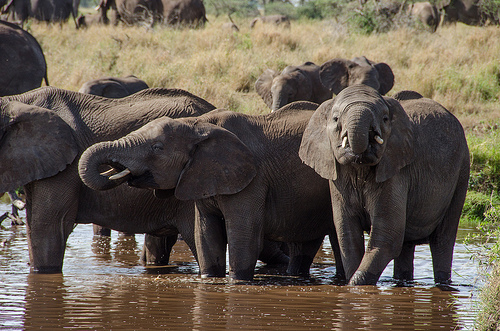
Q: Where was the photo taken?
A: It was taken at the park.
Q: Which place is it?
A: It is a park.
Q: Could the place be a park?
A: Yes, it is a park.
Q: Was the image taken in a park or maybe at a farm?
A: It was taken at a park.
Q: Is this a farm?
A: No, it is a park.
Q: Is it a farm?
A: No, it is a park.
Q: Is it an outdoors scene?
A: Yes, it is outdoors.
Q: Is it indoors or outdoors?
A: It is outdoors.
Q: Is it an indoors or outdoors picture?
A: It is outdoors.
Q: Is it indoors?
A: No, it is outdoors.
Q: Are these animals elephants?
A: Yes, all the animals are elephants.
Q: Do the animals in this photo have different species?
A: No, all the animals are elephants.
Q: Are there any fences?
A: No, there are no fences.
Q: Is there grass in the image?
A: Yes, there is grass.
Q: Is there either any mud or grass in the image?
A: Yes, there is grass.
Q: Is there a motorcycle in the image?
A: No, there are no motorcycles.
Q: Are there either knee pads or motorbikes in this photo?
A: No, there are no motorbikes or knee pads.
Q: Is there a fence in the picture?
A: No, there are no fences.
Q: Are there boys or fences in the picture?
A: No, there are no fences or boys.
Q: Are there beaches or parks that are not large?
A: No, there is a park but it is large.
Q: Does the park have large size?
A: Yes, the park is large.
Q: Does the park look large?
A: Yes, the park is large.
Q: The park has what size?
A: The park is large.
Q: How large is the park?
A: The park is large.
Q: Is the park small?
A: No, the park is large.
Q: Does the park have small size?
A: No, the park is large.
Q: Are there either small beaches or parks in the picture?
A: No, there is a park but it is large.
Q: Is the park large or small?
A: The park is large.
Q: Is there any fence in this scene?
A: No, there are no fences.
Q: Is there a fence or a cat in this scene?
A: No, there are no fences or cats.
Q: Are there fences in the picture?
A: No, there are no fences.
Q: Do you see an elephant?
A: Yes, there is an elephant.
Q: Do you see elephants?
A: Yes, there is an elephant.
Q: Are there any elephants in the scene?
A: Yes, there is an elephant.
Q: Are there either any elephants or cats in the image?
A: Yes, there is an elephant.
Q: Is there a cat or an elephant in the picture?
A: Yes, there is an elephant.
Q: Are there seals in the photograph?
A: No, there are no seals.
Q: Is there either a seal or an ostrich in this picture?
A: No, there are no seals or ostriches.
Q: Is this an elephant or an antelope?
A: This is an elephant.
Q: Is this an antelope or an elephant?
A: This is an elephant.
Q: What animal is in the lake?
A: The elephant is in the lake.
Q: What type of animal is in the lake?
A: The animal is an elephant.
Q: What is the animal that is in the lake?
A: The animal is an elephant.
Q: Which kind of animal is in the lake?
A: The animal is an elephant.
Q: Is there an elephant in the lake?
A: Yes, there is an elephant in the lake.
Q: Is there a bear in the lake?
A: No, there is an elephant in the lake.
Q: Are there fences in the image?
A: No, there are no fences.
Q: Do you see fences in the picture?
A: No, there are no fences.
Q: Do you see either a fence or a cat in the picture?
A: No, there are no fences or cats.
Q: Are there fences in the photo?
A: No, there are no fences.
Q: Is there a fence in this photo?
A: No, there are no fences.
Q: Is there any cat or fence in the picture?
A: No, there are no fences or cats.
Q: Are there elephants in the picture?
A: Yes, there is an elephant.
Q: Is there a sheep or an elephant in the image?
A: Yes, there is an elephant.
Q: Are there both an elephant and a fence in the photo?
A: No, there is an elephant but no fences.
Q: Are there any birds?
A: No, there are no birds.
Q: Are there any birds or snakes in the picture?
A: No, there are no birds or snakes.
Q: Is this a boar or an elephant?
A: This is an elephant.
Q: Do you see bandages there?
A: No, there are no bandages.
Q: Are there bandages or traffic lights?
A: No, there are no bandages or traffic lights.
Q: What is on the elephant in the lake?
A: The trunk is on the elephant.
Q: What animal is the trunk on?
A: The trunk is on the elephant.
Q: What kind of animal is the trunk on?
A: The trunk is on the elephant.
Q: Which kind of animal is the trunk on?
A: The trunk is on the elephant.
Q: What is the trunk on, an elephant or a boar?
A: The trunk is on an elephant.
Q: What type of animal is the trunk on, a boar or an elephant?
A: The trunk is on an elephant.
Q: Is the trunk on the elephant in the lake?
A: Yes, the trunk is on the elephant.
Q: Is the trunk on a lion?
A: No, the trunk is on the elephant.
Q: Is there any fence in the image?
A: No, there are no fences.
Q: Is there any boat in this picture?
A: No, there are no boats.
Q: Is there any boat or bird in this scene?
A: No, there are no boats or birds.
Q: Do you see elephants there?
A: Yes, there is an elephant.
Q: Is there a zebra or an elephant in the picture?
A: Yes, there is an elephant.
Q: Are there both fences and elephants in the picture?
A: No, there is an elephant but no fences.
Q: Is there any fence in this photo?
A: No, there are no fences.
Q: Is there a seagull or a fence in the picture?
A: No, there are no fences or seagulls.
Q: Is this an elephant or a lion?
A: This is an elephant.